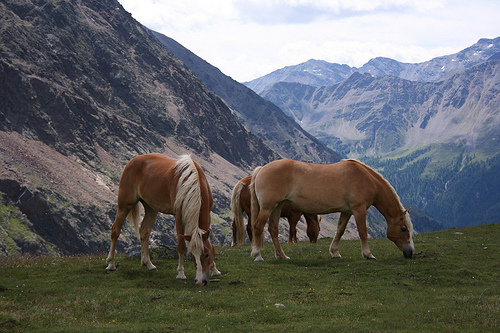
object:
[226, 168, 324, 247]
horse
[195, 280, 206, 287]
nose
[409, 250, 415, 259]
nose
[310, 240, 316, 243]
nose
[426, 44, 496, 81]
snow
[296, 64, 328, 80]
snow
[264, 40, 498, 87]
mountain top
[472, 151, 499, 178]
trees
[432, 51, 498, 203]
mountains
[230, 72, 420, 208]
valley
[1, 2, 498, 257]
mountain range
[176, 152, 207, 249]
mane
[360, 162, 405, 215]
mane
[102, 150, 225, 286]
horse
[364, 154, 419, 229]
ground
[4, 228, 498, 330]
grass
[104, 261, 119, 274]
hooves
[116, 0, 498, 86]
sky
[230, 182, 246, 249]
white tail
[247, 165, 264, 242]
white tail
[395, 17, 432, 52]
white clouds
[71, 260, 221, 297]
shadow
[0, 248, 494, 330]
ground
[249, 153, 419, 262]
horse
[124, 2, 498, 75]
cloud